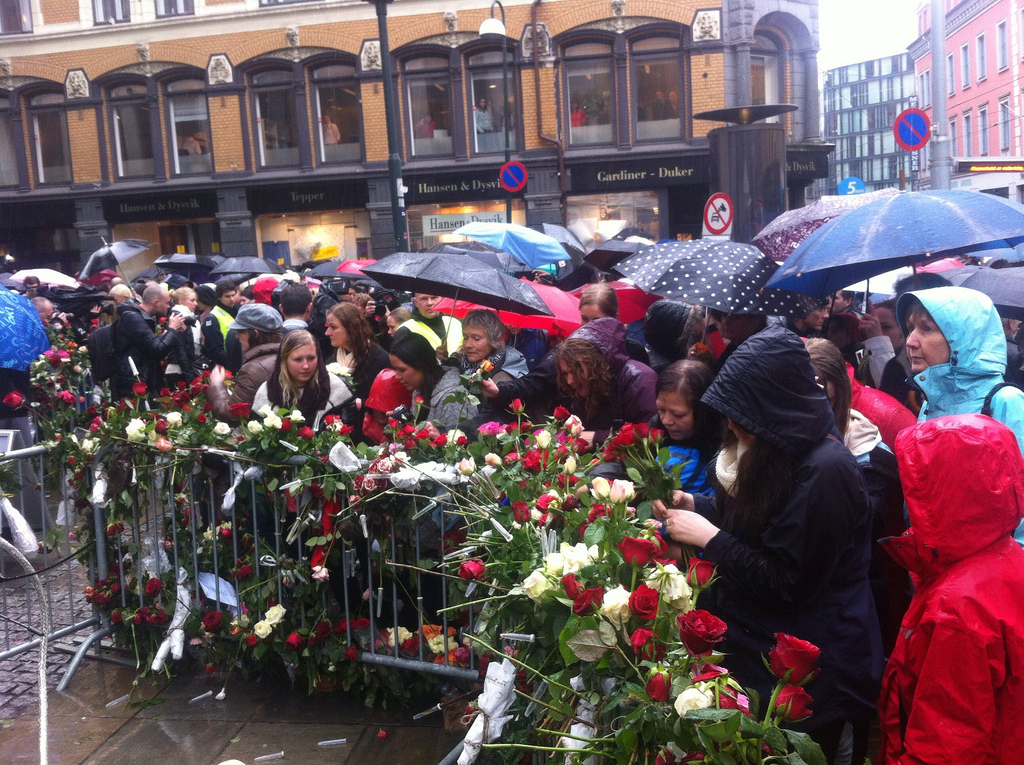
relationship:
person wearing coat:
[880, 401, 1023, 756] [879, 408, 1022, 762]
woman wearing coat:
[892, 286, 1024, 540] [879, 408, 1022, 762]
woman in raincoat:
[654, 326, 878, 759] [700, 322, 890, 742]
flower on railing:
[770, 634, 827, 682] [78, 422, 691, 756]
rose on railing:
[214, 414, 232, 439] [78, 422, 691, 756]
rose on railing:
[164, 410, 184, 429] [78, 422, 691, 756]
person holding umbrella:
[430, 310, 531, 412] [762, 175, 1021, 309]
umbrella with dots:
[603, 233, 831, 333] [687, 256, 703, 274]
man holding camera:
[107, 282, 199, 390] [171, 308, 203, 331]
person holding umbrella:
[430, 309, 531, 411] [353, 251, 558, 328]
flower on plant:
[297, 427, 323, 445] [236, 404, 353, 507]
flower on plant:
[770, 634, 827, 682] [44, 389, 143, 508]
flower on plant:
[770, 634, 827, 682] [514, 526, 700, 644]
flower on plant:
[770, 634, 827, 682] [526, 550, 716, 717]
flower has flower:
[770, 634, 827, 682] [113, 606, 124, 624]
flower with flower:
[770, 634, 827, 682] [770, 634, 827, 682]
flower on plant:
[770, 634, 827, 682] [272, 489, 349, 694]